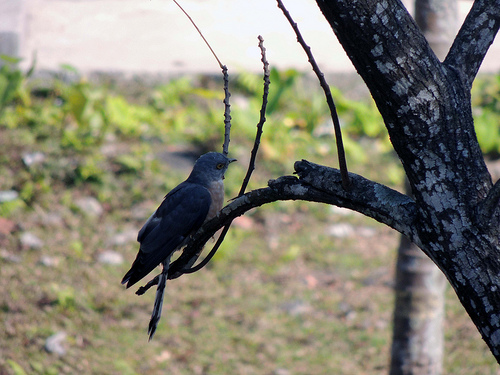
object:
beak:
[223, 157, 238, 167]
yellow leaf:
[275, 112, 297, 132]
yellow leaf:
[257, 135, 276, 164]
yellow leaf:
[311, 139, 332, 158]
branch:
[134, 159, 419, 295]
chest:
[208, 195, 219, 221]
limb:
[480, 179, 500, 228]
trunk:
[315, 0, 500, 367]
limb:
[442, 2, 497, 81]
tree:
[136, 1, 498, 364]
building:
[0, 0, 499, 70]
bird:
[121, 150, 240, 291]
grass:
[0, 187, 500, 374]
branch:
[184, 34, 272, 273]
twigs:
[174, 0, 221, 68]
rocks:
[95, 251, 129, 265]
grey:
[432, 196, 448, 209]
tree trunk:
[305, 1, 498, 363]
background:
[0, 0, 500, 373]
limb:
[317, 0, 500, 363]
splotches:
[436, 139, 447, 156]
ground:
[0, 71, 500, 374]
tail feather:
[125, 252, 159, 288]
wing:
[160, 183, 211, 238]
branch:
[276, 0, 350, 181]